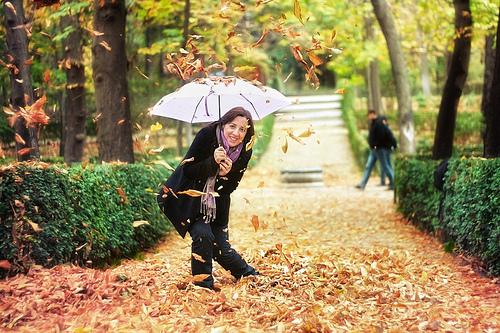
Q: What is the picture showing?
A: It is showing a path.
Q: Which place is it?
A: It is a path.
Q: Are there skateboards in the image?
A: No, there are no skateboards.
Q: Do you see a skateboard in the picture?
A: No, there are no skateboards.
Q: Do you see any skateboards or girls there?
A: No, there are no skateboards or girls.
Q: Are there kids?
A: No, there are no kids.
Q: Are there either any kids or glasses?
A: No, there are no kids or glasses.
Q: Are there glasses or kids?
A: No, there are no kids or glasses.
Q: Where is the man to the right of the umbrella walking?
A: The man is walking on the path.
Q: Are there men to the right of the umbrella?
A: Yes, there is a man to the right of the umbrella.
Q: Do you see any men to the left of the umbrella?
A: No, the man is to the right of the umbrella.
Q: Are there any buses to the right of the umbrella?
A: No, there is a man to the right of the umbrella.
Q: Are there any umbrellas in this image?
A: Yes, there is an umbrella.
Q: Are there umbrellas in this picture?
A: Yes, there is an umbrella.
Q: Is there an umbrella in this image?
A: Yes, there is an umbrella.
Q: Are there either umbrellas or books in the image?
A: Yes, there is an umbrella.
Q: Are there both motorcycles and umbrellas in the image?
A: No, there is an umbrella but no motorcycles.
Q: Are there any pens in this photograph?
A: No, there are no pens.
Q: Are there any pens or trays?
A: No, there are no pens or trays.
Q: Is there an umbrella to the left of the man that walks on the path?
A: Yes, there is an umbrella to the left of the man.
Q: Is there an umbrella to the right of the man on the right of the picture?
A: No, the umbrella is to the left of the man.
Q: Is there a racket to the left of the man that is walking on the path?
A: No, there is an umbrella to the left of the man.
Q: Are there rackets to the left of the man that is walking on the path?
A: No, there is an umbrella to the left of the man.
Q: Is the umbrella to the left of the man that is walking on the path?
A: Yes, the umbrella is to the left of the man.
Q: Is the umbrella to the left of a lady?
A: No, the umbrella is to the left of the man.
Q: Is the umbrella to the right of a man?
A: No, the umbrella is to the left of a man.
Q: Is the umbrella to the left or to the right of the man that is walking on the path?
A: The umbrella is to the left of the man.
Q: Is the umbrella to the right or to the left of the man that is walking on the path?
A: The umbrella is to the left of the man.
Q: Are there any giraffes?
A: No, there are no giraffes.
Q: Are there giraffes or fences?
A: No, there are no giraffes or fences.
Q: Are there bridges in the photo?
A: Yes, there is a bridge.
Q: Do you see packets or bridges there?
A: Yes, there is a bridge.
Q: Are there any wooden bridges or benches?
A: Yes, there is a wood bridge.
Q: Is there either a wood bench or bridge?
A: Yes, there is a wood bridge.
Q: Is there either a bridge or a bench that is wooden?
A: Yes, the bridge is wooden.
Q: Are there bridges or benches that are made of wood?
A: Yes, the bridge is made of wood.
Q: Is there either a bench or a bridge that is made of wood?
A: Yes, the bridge is made of wood.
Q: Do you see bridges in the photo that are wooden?
A: Yes, there is a wood bridge.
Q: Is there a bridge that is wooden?
A: Yes, there is a bridge that is wooden.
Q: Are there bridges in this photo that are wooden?
A: Yes, there is a bridge that is wooden.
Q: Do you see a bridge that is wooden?
A: Yes, there is a bridge that is wooden.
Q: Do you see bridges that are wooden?
A: Yes, there is a bridge that is wooden.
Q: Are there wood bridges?
A: Yes, there is a bridge that is made of wood.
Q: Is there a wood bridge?
A: Yes, there is a bridge that is made of wood.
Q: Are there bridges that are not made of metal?
A: Yes, there is a bridge that is made of wood.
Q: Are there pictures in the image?
A: No, there are no pictures.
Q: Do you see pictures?
A: No, there are no pictures.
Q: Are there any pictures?
A: No, there are no pictures.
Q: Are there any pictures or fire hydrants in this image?
A: No, there are no pictures or fire hydrants.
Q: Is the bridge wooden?
A: Yes, the bridge is wooden.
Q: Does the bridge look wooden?
A: Yes, the bridge is wooden.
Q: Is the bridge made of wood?
A: Yes, the bridge is made of wood.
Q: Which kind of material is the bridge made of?
A: The bridge is made of wood.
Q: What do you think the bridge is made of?
A: The bridge is made of wood.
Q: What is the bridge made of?
A: The bridge is made of wood.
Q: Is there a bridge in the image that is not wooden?
A: No, there is a bridge but it is wooden.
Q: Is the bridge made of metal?
A: No, the bridge is made of wood.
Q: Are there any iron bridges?
A: No, there is a bridge but it is made of wood.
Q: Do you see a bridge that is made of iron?
A: No, there is a bridge but it is made of wood.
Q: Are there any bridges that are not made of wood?
A: No, there is a bridge but it is made of wood.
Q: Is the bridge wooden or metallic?
A: The bridge is wooden.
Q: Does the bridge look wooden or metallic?
A: The bridge is wooden.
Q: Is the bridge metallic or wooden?
A: The bridge is wooden.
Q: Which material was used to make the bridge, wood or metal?
A: The bridge is made of wood.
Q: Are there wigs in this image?
A: No, there are no wigs.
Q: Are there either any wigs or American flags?
A: No, there are no wigs or American flags.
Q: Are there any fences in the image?
A: No, there are no fences.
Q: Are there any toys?
A: No, there are no toys.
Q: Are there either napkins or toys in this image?
A: No, there are no toys or napkins.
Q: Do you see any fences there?
A: No, there are no fences.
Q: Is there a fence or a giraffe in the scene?
A: No, there are no fences or giraffes.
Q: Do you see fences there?
A: No, there are no fences.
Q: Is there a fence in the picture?
A: No, there are no fences.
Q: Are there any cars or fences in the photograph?
A: No, there are no fences or cars.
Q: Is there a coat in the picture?
A: Yes, there is a coat.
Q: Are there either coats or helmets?
A: Yes, there is a coat.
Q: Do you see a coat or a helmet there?
A: Yes, there is a coat.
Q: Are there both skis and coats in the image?
A: No, there is a coat but no skis.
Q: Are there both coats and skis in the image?
A: No, there is a coat but no skis.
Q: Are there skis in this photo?
A: No, there are no skis.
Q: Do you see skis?
A: No, there are no skis.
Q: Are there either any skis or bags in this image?
A: No, there are no skis or bags.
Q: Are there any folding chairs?
A: No, there are no folding chairs.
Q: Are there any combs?
A: No, there are no combs.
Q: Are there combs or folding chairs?
A: No, there are no combs or folding chairs.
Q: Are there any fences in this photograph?
A: No, there are no fences.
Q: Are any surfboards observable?
A: No, there are no surfboards.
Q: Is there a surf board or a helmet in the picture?
A: No, there are no surfboards or helmets.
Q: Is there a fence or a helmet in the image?
A: No, there are no fences or helmets.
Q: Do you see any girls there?
A: No, there are no girls.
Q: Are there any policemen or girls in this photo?
A: No, there are no girls or policemen.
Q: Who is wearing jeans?
A: The man is wearing jeans.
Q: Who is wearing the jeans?
A: The man is wearing jeans.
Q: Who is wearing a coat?
A: The man is wearing a coat.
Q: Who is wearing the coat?
A: The man is wearing a coat.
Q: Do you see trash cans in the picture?
A: No, there are no trash cans.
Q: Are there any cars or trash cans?
A: No, there are no trash cans or cars.